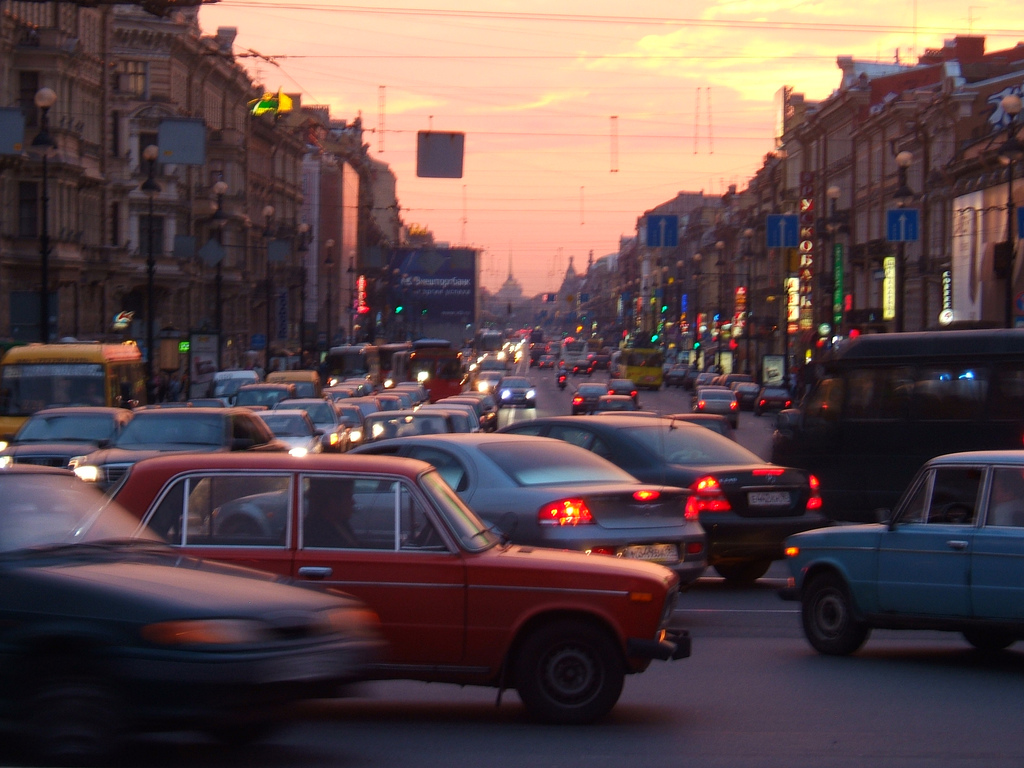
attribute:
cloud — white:
[458, 81, 595, 118]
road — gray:
[303, 331, 1021, 755]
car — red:
[89, 446, 692, 723]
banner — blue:
[886, 202, 919, 248]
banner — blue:
[765, 210, 798, 256]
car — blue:
[786, 441, 1022, 655]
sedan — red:
[58, 450, 692, 721]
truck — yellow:
[4, 340, 145, 434]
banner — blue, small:
[642, 215, 664, 250]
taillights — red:
[689, 474, 821, 514]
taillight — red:
[538, 491, 591, 524]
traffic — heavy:
[0, 318, 1016, 748]